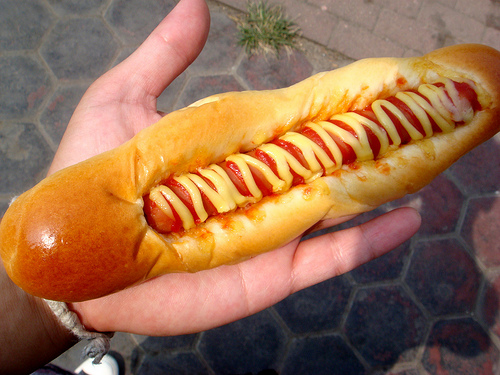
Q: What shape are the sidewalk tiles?
A: Hexagon.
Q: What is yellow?
A: Mustard.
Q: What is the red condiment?
A: Ketchup.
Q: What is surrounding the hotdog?
A: Bread.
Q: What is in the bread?
A: Hotdog.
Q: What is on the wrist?
A: Bracelet?.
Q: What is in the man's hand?
A: Hotdog.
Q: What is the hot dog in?
A: The bun.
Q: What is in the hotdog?
A: Mustard.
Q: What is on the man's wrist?
A: Bracelet.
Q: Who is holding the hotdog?
A: The man.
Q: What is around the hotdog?
A: Bread.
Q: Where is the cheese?
A: Top of the hotdog.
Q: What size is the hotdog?
A: Long.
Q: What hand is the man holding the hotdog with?
A: Left.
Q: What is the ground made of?
A: Brick.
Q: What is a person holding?
A: A hot dog.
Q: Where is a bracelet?
A: Around person's wrist.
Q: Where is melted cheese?
A: On the hot dog.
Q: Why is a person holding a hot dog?
A: To eat it.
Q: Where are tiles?
A: On the ground.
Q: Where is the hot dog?
A: Inside bread.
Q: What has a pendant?
A: The bracelet.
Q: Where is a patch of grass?
A: On the ground.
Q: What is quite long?
A: Hot dog.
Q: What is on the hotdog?
A: Ketchup and cheese.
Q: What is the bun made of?
A: Homemade dough.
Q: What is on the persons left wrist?
A: A bracelet.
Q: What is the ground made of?
A: Hexagonal stones.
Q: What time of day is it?
A: Daytime.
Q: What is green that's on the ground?
A: Patch of grass.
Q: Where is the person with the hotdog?
A: Outside a hot dog stand.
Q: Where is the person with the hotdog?
A: Standing on the sidewalk.